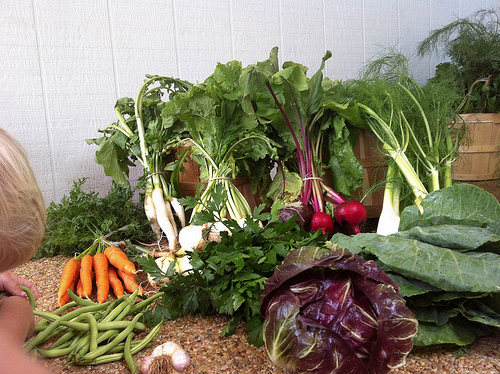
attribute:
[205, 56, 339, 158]
tops — green 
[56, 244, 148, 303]
carrot — orange 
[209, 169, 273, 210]
band — rubber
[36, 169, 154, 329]
carrots — orange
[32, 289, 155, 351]
beans — green 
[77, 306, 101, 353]
pea pod — green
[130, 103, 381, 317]
vegetables — green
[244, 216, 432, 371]
lettuce — purple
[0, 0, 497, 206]
wall — white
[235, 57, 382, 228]
beets — Red 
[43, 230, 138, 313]
carrot — orange 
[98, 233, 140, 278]
carrot root — orange 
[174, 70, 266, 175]
tops — green 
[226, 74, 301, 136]
leaves — green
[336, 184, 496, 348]
leaves — large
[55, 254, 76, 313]
carrot — orange